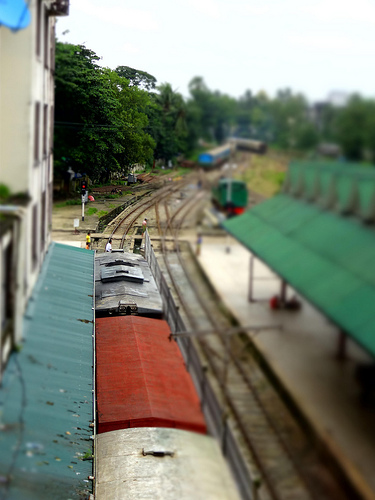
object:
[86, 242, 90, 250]
person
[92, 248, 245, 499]
train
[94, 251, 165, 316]
roof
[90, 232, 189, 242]
split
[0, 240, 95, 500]
roof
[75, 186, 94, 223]
people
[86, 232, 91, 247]
people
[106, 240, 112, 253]
people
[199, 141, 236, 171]
trains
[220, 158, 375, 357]
pavilion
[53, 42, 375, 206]
forest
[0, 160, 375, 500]
station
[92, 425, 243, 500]
roof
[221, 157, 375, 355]
roof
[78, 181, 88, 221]
light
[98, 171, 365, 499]
track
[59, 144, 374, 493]
yard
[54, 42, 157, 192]
trees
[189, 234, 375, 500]
platform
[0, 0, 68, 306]
building